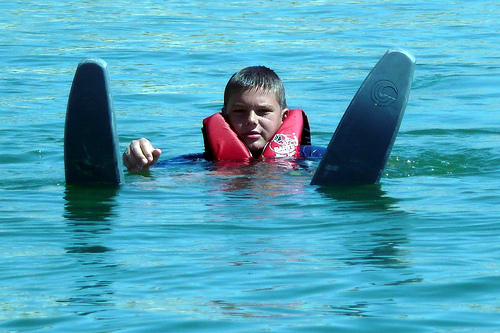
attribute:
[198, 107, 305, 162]
life jacket — red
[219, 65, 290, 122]
hair — short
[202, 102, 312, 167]
vest — lifegaurd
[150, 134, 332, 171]
shirt — blue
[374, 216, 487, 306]
water — blue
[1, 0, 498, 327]
ocean — blue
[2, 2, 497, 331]
water — blue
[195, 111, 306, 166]
life guard — red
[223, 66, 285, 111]
hair — brown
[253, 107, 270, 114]
eye — open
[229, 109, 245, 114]
eye — open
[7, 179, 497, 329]
waters — blue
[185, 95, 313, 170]
life preserver — red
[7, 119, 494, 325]
water — calm